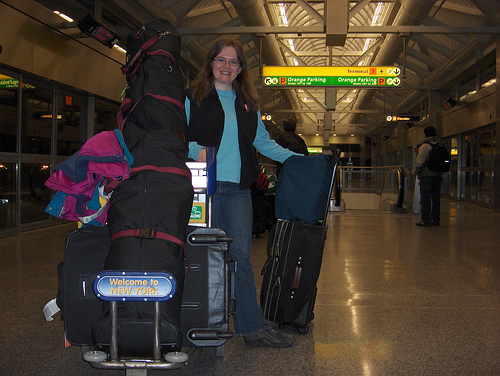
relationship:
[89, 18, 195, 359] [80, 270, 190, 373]
bag on top of trolley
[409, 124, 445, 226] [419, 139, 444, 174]
man standing with backpack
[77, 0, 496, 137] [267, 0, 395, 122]
roof filled with lights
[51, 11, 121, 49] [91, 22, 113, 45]
display with red lights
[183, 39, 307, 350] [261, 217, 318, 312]
grinning lady holding luggage bag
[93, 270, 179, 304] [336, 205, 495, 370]
sign close to floor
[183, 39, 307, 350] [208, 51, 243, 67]
grinning lady wearing glasses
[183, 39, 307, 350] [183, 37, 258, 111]
grinning lady has hair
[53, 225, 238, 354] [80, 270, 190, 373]
luggage on top of trolley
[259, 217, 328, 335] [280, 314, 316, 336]
luggage bag with wheels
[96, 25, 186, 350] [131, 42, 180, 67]
bag has strap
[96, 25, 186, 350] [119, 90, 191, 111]
bag has strap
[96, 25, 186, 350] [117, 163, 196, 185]
bag has strap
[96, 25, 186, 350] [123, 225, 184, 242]
bag has strap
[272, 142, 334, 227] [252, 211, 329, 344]
bag on suitcase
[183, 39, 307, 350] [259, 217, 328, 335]
grinning lady next luggage bag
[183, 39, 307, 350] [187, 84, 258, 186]
grinning lady wears vest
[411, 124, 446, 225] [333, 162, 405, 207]
man next escalator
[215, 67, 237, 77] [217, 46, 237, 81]
grin on face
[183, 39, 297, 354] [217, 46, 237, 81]
grinning lady with face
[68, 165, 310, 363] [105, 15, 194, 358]
side of bag